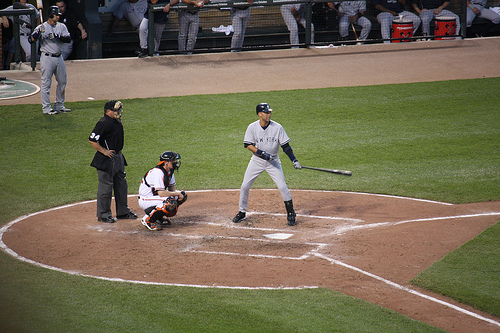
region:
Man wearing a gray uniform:
[226, 92, 304, 231]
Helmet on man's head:
[248, 99, 274, 116]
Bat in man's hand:
[287, 152, 357, 187]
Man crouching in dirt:
[135, 141, 194, 237]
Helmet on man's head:
[150, 148, 183, 170]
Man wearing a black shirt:
[82, 99, 144, 226]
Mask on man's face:
[103, 94, 125, 120]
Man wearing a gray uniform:
[22, 5, 82, 123]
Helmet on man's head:
[44, 5, 66, 20]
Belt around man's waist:
[35, 48, 64, 62]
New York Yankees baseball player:
[231, 101, 353, 225]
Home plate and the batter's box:
[183, 207, 361, 261]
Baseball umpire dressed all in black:
[86, 98, 136, 223]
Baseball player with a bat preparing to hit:
[231, 102, 353, 229]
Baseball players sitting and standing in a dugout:
[134, 0, 491, 58]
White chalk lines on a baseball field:
[0, 185, 417, 290]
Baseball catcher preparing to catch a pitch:
[136, 151, 187, 231]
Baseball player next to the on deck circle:
[27, 3, 73, 118]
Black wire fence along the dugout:
[147, 2, 473, 52]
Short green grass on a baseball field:
[327, 77, 498, 204]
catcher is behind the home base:
[133, 145, 360, 267]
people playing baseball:
[5, 3, 362, 266]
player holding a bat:
[220, 86, 365, 226]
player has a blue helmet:
[225, 95, 305, 235]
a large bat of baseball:
[295, 155, 356, 178]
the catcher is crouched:
[135, 147, 190, 232]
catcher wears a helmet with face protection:
[146, 145, 187, 181]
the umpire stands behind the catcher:
[83, 95, 189, 235]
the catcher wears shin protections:
[131, 147, 192, 232]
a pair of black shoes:
[228, 206, 302, 226]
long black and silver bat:
[295, 159, 366, 179]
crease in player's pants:
[243, 150, 280, 168]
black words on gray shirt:
[245, 133, 295, 145]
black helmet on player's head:
[249, 98, 280, 113]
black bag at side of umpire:
[81, 149, 131, 174]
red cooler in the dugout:
[383, 10, 418, 45]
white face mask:
[107, 96, 130, 113]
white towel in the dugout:
[204, 19, 244, 36]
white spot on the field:
[72, 92, 97, 106]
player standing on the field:
[25, 4, 85, 116]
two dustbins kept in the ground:
[393, 5, 463, 51]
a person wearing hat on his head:
[252, 100, 274, 114]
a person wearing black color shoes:
[231, 203, 297, 235]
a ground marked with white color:
[81, 189, 383, 329]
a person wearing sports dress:
[241, 122, 307, 214]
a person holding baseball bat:
[288, 154, 351, 186]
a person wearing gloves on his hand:
[249, 146, 269, 161]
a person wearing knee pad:
[155, 197, 177, 216]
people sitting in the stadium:
[143, 13, 373, 48]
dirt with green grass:
[341, 67, 472, 188]